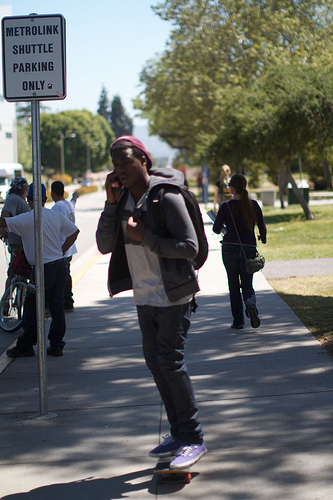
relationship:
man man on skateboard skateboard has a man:
[95, 135, 211, 461] [156, 443, 196, 487]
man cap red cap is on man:
[95, 135, 211, 461] [107, 134, 155, 167]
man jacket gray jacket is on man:
[95, 135, 211, 461] [97, 164, 200, 301]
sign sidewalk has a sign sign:
[0, 16, 69, 108] [0, 16, 69, 108]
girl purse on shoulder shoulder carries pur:
[209, 170, 269, 330] [224, 198, 268, 271]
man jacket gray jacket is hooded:
[95, 135, 211, 461] [97, 164, 200, 301]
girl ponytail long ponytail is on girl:
[209, 170, 269, 330] [241, 188, 258, 232]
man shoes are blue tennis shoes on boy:
[95, 135, 211, 461] [150, 431, 210, 471]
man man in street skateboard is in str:
[95, 135, 211, 461] [156, 443, 196, 487]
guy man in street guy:
[0, 180, 79, 357] [0, 180, 79, 357]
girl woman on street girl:
[209, 170, 269, 330] [209, 170, 269, 330]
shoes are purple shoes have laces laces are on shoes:
[150, 431, 210, 471] [176, 444, 195, 459]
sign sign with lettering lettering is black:
[0, 16, 69, 108] [4, 24, 58, 90]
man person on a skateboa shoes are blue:
[95, 135, 211, 461] [150, 431, 210, 471]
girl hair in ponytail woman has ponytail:
[209, 170, 269, 330] [241, 188, 258, 232]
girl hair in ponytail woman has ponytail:
[209, 170, 269, 330] [221, 167, 229, 186]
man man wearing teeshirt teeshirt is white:
[95, 135, 211, 461] [114, 188, 190, 307]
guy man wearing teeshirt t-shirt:
[0, 180, 79, 357] [2, 204, 79, 263]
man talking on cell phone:
[95, 135, 211, 461] [107, 160, 122, 187]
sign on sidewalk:
[0, 16, 69, 108] [3, 179, 279, 497]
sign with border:
[0, 16, 69, 108] [7, 14, 68, 102]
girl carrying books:
[209, 172, 269, 326] [204, 200, 228, 236]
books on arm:
[204, 200, 228, 236] [209, 193, 227, 230]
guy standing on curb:
[0, 180, 79, 357] [1, 336, 16, 370]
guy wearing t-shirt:
[0, 180, 79, 357] [2, 204, 79, 263]